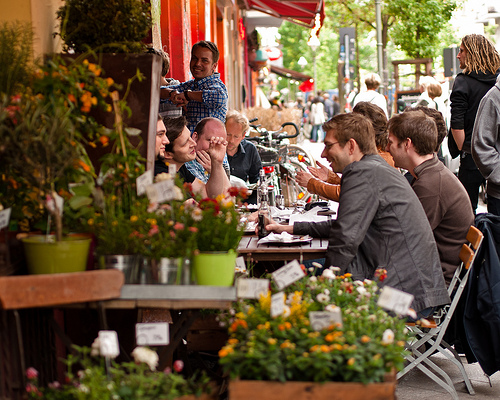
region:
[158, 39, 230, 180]
a smiling man in a blue and white plaid shirt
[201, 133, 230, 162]
a person's hand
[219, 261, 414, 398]
yellow and red flowers in a box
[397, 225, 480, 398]
a metal and wood chair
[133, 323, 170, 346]
a white card with writing on it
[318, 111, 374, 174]
a side view of a man's face and head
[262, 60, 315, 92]
a red awning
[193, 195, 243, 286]
a green flower pot with red and yellow flowers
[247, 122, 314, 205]
a group of parked bicycles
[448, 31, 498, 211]
a man in black shirt and pants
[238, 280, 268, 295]
A small white sign.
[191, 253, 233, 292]
A small green pot.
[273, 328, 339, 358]
A group of orange flowers.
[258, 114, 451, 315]
A man sitting down.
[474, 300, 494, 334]
Part of a blue jacket.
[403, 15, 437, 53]
Part of a green tree.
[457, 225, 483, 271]
Part of a chair.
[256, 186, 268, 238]
A clear bottle.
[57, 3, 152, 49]
Part of a round tree.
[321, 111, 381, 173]
The man's head.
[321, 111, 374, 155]
the light brown hair on a head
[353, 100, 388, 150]
the light brown hair on a head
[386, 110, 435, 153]
the light brown hair on a head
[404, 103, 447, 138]
the light brown hair on a head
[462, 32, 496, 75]
the light brown hair on a head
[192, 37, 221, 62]
the light brown hair on a head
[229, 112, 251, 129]
the light brown hair on a head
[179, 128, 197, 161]
the face of a person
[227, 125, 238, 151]
the face of a person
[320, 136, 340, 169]
the face of a person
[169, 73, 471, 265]
people eating at a restaurant ourdoors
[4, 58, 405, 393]
plants for sale on the sidewalk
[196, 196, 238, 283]
green potting plant with flowers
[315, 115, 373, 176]
man wearing eye glasses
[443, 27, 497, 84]
man with his hair in dread locks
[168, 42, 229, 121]
man wearing a blue plaid shirt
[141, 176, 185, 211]
little white signs in the plants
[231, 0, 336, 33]
red awning above sidewalk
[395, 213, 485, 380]
silver chair with wooden slats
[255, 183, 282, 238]
glass bottle with a black label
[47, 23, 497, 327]
a busy scene at a restaurant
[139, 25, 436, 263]
these people are enjoying a meal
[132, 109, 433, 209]
these people are socializing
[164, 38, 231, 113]
this guy looks happy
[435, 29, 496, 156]
this man is looking into the area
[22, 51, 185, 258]
flowers in the area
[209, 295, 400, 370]
flowers for sale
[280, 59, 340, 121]
people in the distance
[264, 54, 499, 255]
a busy street scene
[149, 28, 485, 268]
a lot of activity in the area